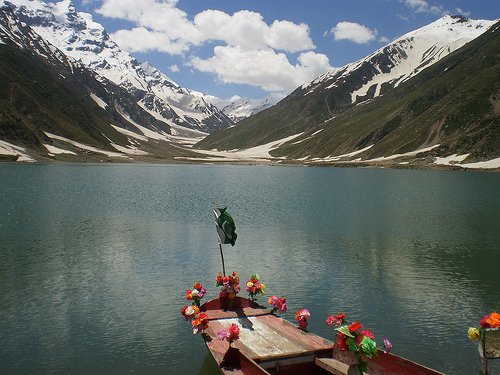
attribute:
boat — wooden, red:
[199, 292, 453, 374]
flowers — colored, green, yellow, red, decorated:
[216, 269, 288, 312]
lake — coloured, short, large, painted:
[1, 162, 497, 373]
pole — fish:
[216, 238, 231, 276]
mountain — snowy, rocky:
[192, 12, 499, 169]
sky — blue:
[9, 1, 499, 99]